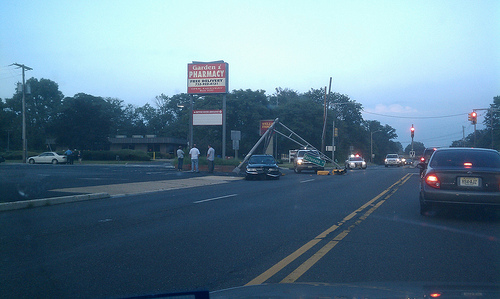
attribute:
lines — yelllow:
[271, 177, 409, 284]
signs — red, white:
[179, 50, 279, 171]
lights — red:
[398, 115, 479, 132]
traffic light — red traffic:
[410, 122, 415, 136]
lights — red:
[455, 109, 490, 129]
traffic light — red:
[468, 110, 480, 125]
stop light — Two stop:
[410, 124, 416, 136]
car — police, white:
[289, 146, 330, 176]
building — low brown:
[110, 129, 185, 156]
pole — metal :
[216, 97, 228, 166]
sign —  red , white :
[186, 55, 231, 100]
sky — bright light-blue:
[113, 24, 347, 60]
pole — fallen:
[235, 118, 343, 181]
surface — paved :
[244, 196, 420, 282]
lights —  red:
[345, 148, 361, 161]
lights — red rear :
[426, 169, 440, 185]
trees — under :
[52, 86, 140, 129]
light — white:
[290, 155, 311, 179]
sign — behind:
[177, 54, 278, 144]